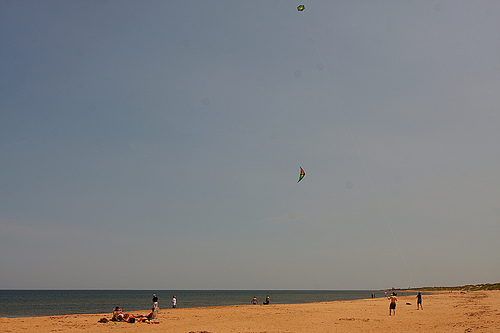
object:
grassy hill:
[384, 281, 499, 292]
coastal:
[0, 210, 499, 332]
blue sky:
[1, 1, 498, 292]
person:
[131, 307, 158, 320]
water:
[0, 288, 427, 318]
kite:
[297, 164, 309, 183]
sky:
[0, 0, 500, 285]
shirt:
[415, 295, 422, 303]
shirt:
[170, 297, 176, 305]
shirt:
[152, 295, 158, 301]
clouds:
[0, 1, 499, 280]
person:
[112, 305, 136, 323]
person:
[136, 314, 161, 325]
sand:
[0, 289, 499, 331]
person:
[152, 293, 158, 307]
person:
[170, 294, 177, 309]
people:
[151, 293, 160, 310]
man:
[386, 291, 399, 315]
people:
[414, 290, 423, 310]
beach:
[0, 289, 500, 331]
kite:
[296, 4, 306, 11]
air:
[1, 0, 499, 332]